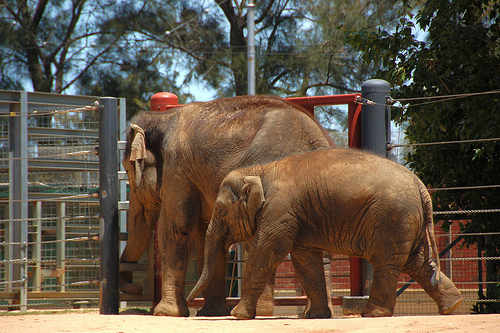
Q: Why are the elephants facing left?
A: Walking to dinner.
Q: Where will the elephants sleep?
A: On sand.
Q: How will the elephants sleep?
A: Naked.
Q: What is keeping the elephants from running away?
A: A pen.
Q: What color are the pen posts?
A: Grey.